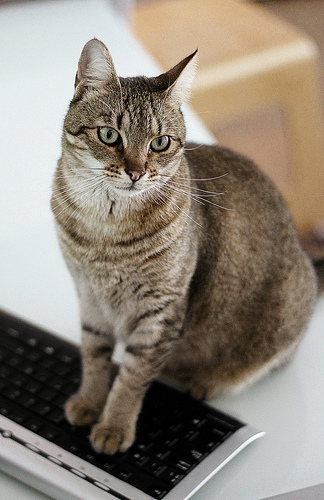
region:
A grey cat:
[50, 30, 323, 497]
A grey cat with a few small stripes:
[15, 24, 298, 391]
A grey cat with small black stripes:
[8, 1, 267, 404]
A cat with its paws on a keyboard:
[9, 34, 299, 455]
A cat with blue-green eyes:
[58, 102, 211, 183]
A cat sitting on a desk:
[54, 37, 315, 387]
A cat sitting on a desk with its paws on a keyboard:
[31, 23, 302, 446]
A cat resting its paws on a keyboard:
[25, 20, 304, 468]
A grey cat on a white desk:
[27, 39, 286, 466]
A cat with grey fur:
[38, 35, 323, 483]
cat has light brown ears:
[72, 32, 194, 123]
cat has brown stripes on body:
[66, 165, 170, 363]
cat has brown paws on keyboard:
[53, 374, 147, 473]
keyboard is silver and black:
[0, 342, 265, 441]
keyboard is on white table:
[13, 301, 251, 498]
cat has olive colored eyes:
[102, 119, 190, 180]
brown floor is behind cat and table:
[181, 32, 320, 176]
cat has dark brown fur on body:
[204, 140, 268, 316]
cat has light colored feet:
[220, 333, 304, 407]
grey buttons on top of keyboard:
[16, 434, 102, 499]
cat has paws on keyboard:
[62, 353, 145, 470]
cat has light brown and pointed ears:
[58, 32, 156, 98]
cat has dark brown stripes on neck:
[58, 190, 235, 302]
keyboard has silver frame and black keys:
[14, 325, 253, 498]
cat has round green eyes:
[88, 116, 173, 159]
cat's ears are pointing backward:
[78, 45, 212, 104]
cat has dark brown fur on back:
[186, 146, 322, 351]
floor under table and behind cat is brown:
[162, 33, 311, 187]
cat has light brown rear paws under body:
[231, 325, 304, 405]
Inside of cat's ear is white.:
[81, 56, 124, 99]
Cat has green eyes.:
[91, 121, 175, 153]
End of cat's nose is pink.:
[128, 166, 150, 185]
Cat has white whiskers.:
[61, 162, 231, 200]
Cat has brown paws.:
[44, 382, 149, 467]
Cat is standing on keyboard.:
[24, 371, 147, 452]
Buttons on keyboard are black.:
[10, 332, 183, 476]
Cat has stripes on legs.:
[62, 303, 219, 384]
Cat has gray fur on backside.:
[220, 269, 305, 330]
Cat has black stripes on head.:
[112, 87, 188, 156]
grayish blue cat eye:
[96, 122, 120, 147]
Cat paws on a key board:
[62, 384, 141, 456]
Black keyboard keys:
[146, 411, 188, 474]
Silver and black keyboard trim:
[41, 451, 71, 496]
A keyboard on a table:
[220, 409, 280, 461]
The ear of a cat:
[70, 33, 117, 102]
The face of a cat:
[65, 77, 205, 210]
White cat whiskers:
[84, 169, 107, 212]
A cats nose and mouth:
[121, 159, 149, 202]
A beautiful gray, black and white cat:
[41, 33, 243, 322]